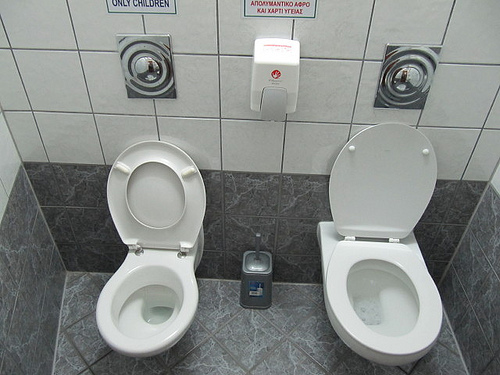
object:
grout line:
[0, 47, 116, 52]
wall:
[0, 0, 500, 375]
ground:
[54, 270, 469, 375]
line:
[2, 110, 500, 131]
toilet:
[94, 140, 205, 359]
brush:
[255, 234, 261, 259]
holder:
[241, 233, 273, 308]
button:
[391, 64, 423, 94]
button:
[135, 57, 161, 84]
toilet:
[316, 122, 442, 367]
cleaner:
[241, 233, 273, 309]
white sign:
[243, 1, 314, 17]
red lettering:
[249, 1, 310, 14]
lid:
[106, 141, 206, 251]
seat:
[107, 140, 205, 248]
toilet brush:
[239, 232, 273, 309]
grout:
[220, 119, 223, 171]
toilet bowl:
[94, 250, 200, 357]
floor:
[51, 271, 469, 375]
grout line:
[78, 53, 106, 164]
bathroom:
[0, 0, 500, 375]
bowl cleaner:
[240, 250, 272, 309]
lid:
[328, 123, 438, 240]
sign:
[244, 0, 316, 19]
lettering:
[250, 0, 311, 13]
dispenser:
[249, 39, 300, 114]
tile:
[0, 0, 500, 375]